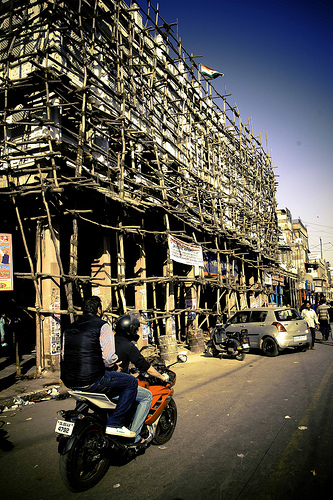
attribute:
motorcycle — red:
[54, 353, 186, 492]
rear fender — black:
[56, 414, 102, 455]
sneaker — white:
[105, 425, 135, 439]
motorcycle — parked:
[205, 321, 249, 361]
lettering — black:
[57, 423, 69, 433]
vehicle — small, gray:
[213, 306, 311, 357]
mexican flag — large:
[196, 64, 223, 79]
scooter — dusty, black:
[201, 320, 251, 362]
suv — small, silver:
[208, 308, 313, 358]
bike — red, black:
[50, 351, 187, 492]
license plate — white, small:
[54, 418, 74, 437]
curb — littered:
[1, 384, 62, 415]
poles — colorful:
[209, 244, 331, 315]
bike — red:
[117, 336, 173, 447]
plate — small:
[45, 404, 100, 442]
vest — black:
[43, 308, 122, 407]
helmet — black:
[114, 304, 150, 345]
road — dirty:
[170, 372, 324, 468]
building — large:
[33, 8, 303, 293]